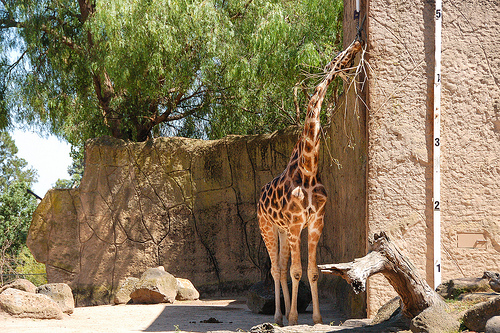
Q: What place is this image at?
A: It is at the zoo.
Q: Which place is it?
A: It is a zoo.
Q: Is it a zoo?
A: Yes, it is a zoo.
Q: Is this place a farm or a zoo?
A: It is a zoo.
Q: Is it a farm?
A: No, it is a zoo.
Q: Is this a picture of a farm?
A: No, the picture is showing a zoo.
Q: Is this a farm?
A: No, it is a zoo.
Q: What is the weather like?
A: It is clear.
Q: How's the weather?
A: It is clear.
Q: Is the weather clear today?
A: Yes, it is clear.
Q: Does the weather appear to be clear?
A: Yes, it is clear.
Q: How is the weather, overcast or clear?
A: It is clear.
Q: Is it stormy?
A: No, it is clear.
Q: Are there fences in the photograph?
A: No, there are no fences.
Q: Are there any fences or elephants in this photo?
A: No, there are no fences or elephants.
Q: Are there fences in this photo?
A: No, there are no fences.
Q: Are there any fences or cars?
A: No, there are no fences or cars.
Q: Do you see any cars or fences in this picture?
A: No, there are no fences or cars.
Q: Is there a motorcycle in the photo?
A: No, there are no motorcycles.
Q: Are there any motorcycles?
A: No, there are no motorcycles.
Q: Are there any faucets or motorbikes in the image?
A: No, there are no motorbikes or faucets.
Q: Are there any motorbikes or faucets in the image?
A: No, there are no motorbikes or faucets.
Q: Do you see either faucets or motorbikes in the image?
A: No, there are no motorbikes or faucets.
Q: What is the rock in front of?
A: The rock is in front of the wall.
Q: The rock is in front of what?
A: The rock is in front of the wall.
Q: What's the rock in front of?
A: The rock is in front of the wall.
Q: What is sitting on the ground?
A: The rock is sitting on the ground.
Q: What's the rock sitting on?
A: The rock is sitting on the ground.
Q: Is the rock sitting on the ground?
A: Yes, the rock is sitting on the ground.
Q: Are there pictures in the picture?
A: No, there are no pictures.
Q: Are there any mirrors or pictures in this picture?
A: No, there are no pictures or mirrors.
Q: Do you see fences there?
A: No, there are no fences.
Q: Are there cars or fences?
A: No, there are no fences or cars.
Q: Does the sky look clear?
A: Yes, the sky is clear.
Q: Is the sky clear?
A: Yes, the sky is clear.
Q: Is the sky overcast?
A: No, the sky is clear.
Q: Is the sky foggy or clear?
A: The sky is clear.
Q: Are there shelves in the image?
A: No, there are no shelves.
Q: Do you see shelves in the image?
A: No, there are no shelves.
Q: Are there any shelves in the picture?
A: No, there are no shelves.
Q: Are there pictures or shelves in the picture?
A: No, there are no shelves or pictures.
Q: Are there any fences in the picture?
A: No, there are no fences.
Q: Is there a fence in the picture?
A: No, there are no fences.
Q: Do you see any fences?
A: No, there are no fences.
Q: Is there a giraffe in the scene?
A: Yes, there is a giraffe.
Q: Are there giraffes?
A: Yes, there is a giraffe.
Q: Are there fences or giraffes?
A: Yes, there is a giraffe.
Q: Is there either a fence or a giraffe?
A: Yes, there is a giraffe.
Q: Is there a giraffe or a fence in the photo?
A: Yes, there is a giraffe.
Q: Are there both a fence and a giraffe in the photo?
A: No, there is a giraffe but no fences.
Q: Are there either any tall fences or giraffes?
A: Yes, there is a tall giraffe.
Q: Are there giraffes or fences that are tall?
A: Yes, the giraffe is tall.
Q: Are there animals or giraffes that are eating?
A: Yes, the giraffe is eating.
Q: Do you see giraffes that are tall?
A: Yes, there is a tall giraffe.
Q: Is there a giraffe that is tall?
A: Yes, there is a giraffe that is tall.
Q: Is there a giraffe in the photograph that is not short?
A: Yes, there is a tall giraffe.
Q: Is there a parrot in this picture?
A: No, there are no parrots.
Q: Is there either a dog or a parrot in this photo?
A: No, there are no parrots or dogs.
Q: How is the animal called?
A: The animal is a giraffe.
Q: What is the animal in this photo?
A: The animal is a giraffe.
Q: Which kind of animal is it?
A: The animal is a giraffe.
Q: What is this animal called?
A: This is a giraffe.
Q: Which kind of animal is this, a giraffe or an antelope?
A: This is a giraffe.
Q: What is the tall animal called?
A: The animal is a giraffe.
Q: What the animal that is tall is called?
A: The animal is a giraffe.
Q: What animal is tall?
A: The animal is a giraffe.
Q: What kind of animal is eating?
A: The animal is a giraffe.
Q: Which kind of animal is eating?
A: The animal is a giraffe.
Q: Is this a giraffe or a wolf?
A: This is a giraffe.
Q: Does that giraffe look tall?
A: Yes, the giraffe is tall.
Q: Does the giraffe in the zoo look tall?
A: Yes, the giraffe is tall.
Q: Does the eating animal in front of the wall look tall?
A: Yes, the giraffe is tall.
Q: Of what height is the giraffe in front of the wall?
A: The giraffe is tall.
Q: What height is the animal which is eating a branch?
A: The giraffe is tall.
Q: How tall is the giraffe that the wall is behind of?
A: The giraffe is tall.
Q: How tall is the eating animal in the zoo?
A: The giraffe is tall.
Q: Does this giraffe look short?
A: No, the giraffe is tall.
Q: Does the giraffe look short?
A: No, the giraffe is tall.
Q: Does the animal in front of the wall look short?
A: No, the giraffe is tall.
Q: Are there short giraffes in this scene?
A: No, there is a giraffe but it is tall.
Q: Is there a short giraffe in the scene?
A: No, there is a giraffe but it is tall.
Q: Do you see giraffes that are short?
A: No, there is a giraffe but it is tall.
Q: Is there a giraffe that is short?
A: No, there is a giraffe but it is tall.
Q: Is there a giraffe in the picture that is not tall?
A: No, there is a giraffe but it is tall.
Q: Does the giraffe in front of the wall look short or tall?
A: The giraffe is tall.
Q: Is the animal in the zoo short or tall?
A: The giraffe is tall.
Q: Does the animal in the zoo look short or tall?
A: The giraffe is tall.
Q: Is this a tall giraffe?
A: Yes, this is a tall giraffe.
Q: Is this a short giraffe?
A: No, this is a tall giraffe.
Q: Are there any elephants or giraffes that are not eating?
A: No, there is a giraffe but it is eating.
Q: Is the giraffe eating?
A: Yes, the giraffe is eating.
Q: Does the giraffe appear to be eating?
A: Yes, the giraffe is eating.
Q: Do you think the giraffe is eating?
A: Yes, the giraffe is eating.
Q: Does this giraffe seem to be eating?
A: Yes, the giraffe is eating.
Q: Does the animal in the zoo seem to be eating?
A: Yes, the giraffe is eating.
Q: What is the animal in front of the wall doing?
A: The giraffe is eating.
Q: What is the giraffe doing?
A: The giraffe is eating.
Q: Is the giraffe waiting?
A: No, the giraffe is eating.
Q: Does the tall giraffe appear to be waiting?
A: No, the giraffe is eating.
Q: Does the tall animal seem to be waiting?
A: No, the giraffe is eating.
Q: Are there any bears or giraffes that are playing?
A: No, there is a giraffe but it is eating.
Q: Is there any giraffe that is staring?
A: No, there is a giraffe but it is eating.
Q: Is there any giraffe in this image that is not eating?
A: No, there is a giraffe but it is eating.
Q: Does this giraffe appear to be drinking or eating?
A: The giraffe is eating.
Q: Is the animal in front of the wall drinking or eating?
A: The giraffe is eating.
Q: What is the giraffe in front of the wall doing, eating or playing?
A: The giraffe is eating.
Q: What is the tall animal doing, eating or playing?
A: The giraffe is eating.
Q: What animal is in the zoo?
A: The giraffe is in the zoo.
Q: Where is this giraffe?
A: The giraffe is in the zoo.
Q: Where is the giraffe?
A: The giraffe is in the zoo.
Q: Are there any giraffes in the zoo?
A: Yes, there is a giraffe in the zoo.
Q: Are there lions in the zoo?
A: No, there is a giraffe in the zoo.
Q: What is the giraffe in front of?
A: The giraffe is in front of the wall.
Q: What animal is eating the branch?
A: The animal is a giraffe.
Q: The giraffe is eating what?
A: The giraffe is eating a branch.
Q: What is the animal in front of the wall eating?
A: The giraffe is eating a branch.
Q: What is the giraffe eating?
A: The giraffe is eating a branch.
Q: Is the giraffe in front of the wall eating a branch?
A: Yes, the giraffe is eating a branch.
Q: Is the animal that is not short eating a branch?
A: Yes, the giraffe is eating a branch.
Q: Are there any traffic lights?
A: No, there are no traffic lights.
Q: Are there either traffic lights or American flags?
A: No, there are no traffic lights or American flags.